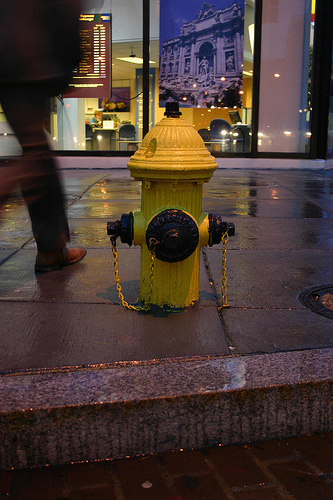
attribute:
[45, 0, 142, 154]
window — large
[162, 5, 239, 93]
monument — famous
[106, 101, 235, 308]
hydrant — fire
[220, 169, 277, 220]
sidewalk — wet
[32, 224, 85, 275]
boot — brown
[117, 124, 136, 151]
chair — desk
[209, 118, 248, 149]
chair — blue, bright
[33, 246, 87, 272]
shoe — brown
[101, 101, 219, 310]
hydrant — yellow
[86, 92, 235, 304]
fire hyrdant — yellow and black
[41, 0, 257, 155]
window — large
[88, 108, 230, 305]
hydrant — fire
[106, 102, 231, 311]
fire hydrant — old, yellow and black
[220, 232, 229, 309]
chain — yellow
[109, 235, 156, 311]
chain — yellow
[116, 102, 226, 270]
hydrant — yellow, black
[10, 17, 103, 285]
image — blurred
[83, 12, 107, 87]
sign — informational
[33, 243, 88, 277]
boot — brown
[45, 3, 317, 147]
window — glass